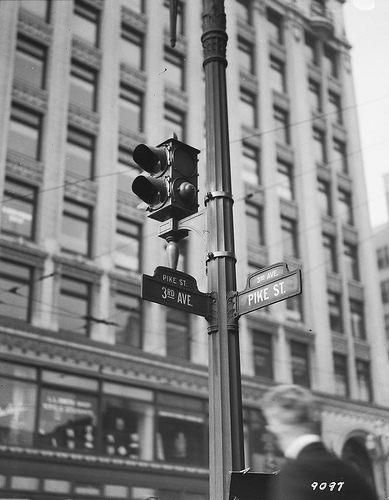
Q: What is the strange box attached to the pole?
A: A stoplight.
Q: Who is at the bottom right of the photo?
A: A business man.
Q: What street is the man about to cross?
A: 3rd. Ave.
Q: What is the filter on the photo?
A: Black and white.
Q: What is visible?
A: A post.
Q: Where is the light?
A: Above the ground.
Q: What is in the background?
A: Windows.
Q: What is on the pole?
A: Signs.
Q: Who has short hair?
A: A man.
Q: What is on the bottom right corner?
A: A number.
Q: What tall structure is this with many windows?
A: Building.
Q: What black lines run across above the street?
A: Power lines.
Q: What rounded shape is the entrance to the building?
A: ARched.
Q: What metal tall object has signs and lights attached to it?
A: Pole.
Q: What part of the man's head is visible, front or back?
A: Back.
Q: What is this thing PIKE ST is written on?
A: Sign.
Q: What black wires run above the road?
A: Power lines.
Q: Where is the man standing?
A: Corner of 3rd Ave. and Pike St.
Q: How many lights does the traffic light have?
A: Two.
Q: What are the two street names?
A: Pike St and 3rd Ave.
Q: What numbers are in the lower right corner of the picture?
A: 9097.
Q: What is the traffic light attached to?
A: A lamp post.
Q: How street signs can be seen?
A: Two.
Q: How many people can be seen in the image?
A: One.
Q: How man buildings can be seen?
A: Two.